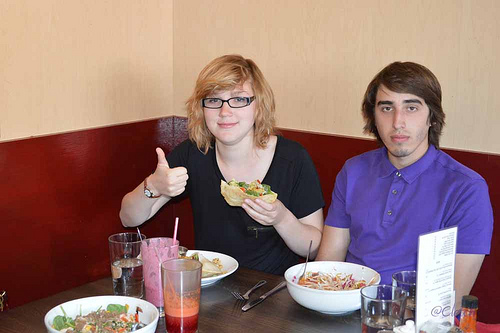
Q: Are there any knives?
A: Yes, there is a knife.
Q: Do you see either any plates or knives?
A: Yes, there is a knife.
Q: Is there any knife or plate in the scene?
A: Yes, there is a knife.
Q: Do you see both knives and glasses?
A: Yes, there are both a knife and glasses.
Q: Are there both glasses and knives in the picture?
A: Yes, there are both a knife and glasses.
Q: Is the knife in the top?
A: No, the knife is in the bottom of the image.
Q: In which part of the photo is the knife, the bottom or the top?
A: The knife is in the bottom of the image.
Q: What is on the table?
A: The knife is on the table.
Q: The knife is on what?
A: The knife is on the table.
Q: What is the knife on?
A: The knife is on the table.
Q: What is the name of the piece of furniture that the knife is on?
A: The piece of furniture is a table.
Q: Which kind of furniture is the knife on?
A: The knife is on the table.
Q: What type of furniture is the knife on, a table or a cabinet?
A: The knife is on a table.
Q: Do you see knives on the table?
A: Yes, there is a knife on the table.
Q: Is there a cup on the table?
A: No, there is a knife on the table.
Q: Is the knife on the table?
A: Yes, the knife is on the table.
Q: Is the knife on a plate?
A: No, the knife is on the table.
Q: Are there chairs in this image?
A: No, there are no chairs.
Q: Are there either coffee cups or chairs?
A: No, there are no chairs or coffee cups.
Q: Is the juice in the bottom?
A: Yes, the juice is in the bottom of the image.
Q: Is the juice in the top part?
A: No, the juice is in the bottom of the image.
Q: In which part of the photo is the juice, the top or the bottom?
A: The juice is in the bottom of the image.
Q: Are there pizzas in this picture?
A: No, there are no pizzas.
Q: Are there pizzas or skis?
A: No, there are no pizzas or skis.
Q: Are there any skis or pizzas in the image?
A: No, there are no pizzas or skis.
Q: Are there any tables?
A: Yes, there is a table.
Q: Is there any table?
A: Yes, there is a table.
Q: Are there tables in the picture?
A: Yes, there is a table.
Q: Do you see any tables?
A: Yes, there is a table.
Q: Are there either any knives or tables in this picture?
A: Yes, there is a table.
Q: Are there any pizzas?
A: No, there are no pizzas.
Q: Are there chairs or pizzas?
A: No, there are no pizzas or chairs.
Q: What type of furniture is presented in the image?
A: The furniture is a table.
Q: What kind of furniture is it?
A: The piece of furniture is a table.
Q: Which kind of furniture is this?
A: That is a table.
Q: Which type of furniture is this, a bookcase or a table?
A: That is a table.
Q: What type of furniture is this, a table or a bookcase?
A: That is a table.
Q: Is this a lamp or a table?
A: This is a table.